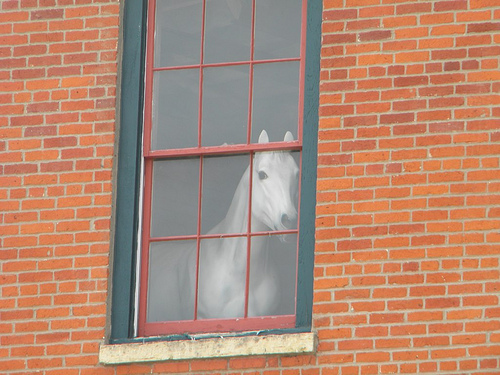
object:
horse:
[170, 124, 300, 320]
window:
[93, 2, 325, 369]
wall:
[2, 1, 496, 373]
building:
[4, 1, 499, 372]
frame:
[106, 0, 326, 349]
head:
[235, 125, 300, 253]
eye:
[252, 167, 270, 183]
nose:
[278, 207, 297, 232]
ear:
[254, 125, 275, 149]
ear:
[279, 129, 299, 150]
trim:
[133, 1, 308, 335]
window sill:
[95, 329, 323, 369]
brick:
[38, 157, 77, 177]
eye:
[289, 166, 301, 184]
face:
[247, 158, 298, 238]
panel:
[204, 66, 251, 146]